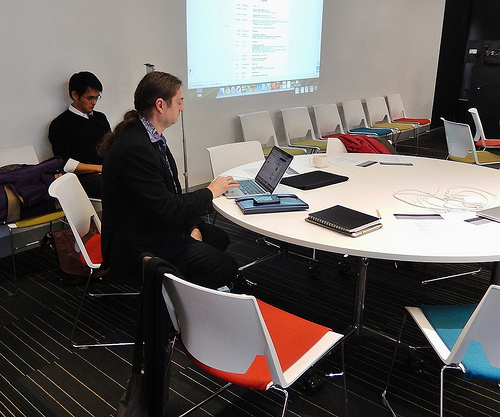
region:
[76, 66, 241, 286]
Man sitting at table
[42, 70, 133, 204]
Man wearing a black sweater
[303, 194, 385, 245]
Notebooks on the table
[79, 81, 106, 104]
Eyeglasses on man's face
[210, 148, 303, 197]
Laptop on the table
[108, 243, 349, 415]
Chair next to man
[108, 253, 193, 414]
Bag hanging on chair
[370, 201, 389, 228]
Pencil on the table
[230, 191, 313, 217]
Notebook on the table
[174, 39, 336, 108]
Projection on the wall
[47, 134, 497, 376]
chairs and table in room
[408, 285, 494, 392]
chair with blue seat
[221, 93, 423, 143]
row of chairs on wall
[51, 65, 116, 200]
man sitting against the wall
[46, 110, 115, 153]
sweater on the man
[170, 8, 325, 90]
image on the screen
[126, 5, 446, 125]
screen for projecting images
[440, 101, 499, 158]
chairs facing away from desk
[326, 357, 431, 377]
wheels on the table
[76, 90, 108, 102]
glasses on the man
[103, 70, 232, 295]
a man with a pony tail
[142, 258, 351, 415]
an orange chair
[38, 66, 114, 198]
a man in a sweater and button down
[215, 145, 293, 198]
a silver laptop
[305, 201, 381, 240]
a pile of spiral bound notebooks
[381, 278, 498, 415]
a blue seat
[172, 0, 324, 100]
a business related projection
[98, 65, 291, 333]
a well dressed man on his laptop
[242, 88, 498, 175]
a row of empty seats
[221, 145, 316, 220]
a laptop and notebook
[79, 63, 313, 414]
middle aged long haired dude, @ a meeting, @ a job where he'd rather not be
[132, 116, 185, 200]
lavender patterned button down shirt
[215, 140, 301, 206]
macbook air, i think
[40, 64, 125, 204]
younger guy, much happier member of corporate culture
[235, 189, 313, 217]
perhaps an ipad, a kindle, or even a notebook in a leather case, topped by a mobilephone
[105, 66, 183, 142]
brown hair, semi-professional ponytail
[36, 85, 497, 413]
white chairs with nicely colourful off-primary seats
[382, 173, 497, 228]
white cable, messy but untangled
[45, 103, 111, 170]
more contemporary, certainly more pleased, white button down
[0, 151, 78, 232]
it's a bag, even though it looks like someone's collapsed across two chairs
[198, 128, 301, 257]
the laptop is on the table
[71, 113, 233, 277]
the jacket is black